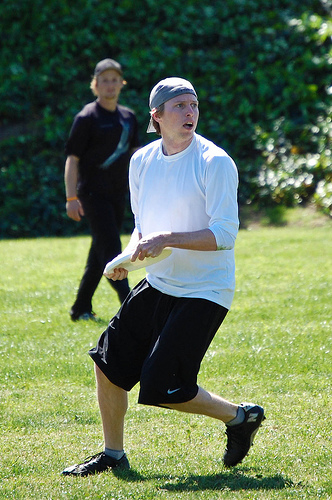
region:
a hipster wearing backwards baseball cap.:
[144, 77, 217, 145]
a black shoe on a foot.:
[217, 402, 269, 464]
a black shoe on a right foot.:
[58, 447, 135, 483]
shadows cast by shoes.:
[109, 466, 296, 499]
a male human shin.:
[90, 361, 131, 451]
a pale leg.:
[154, 386, 238, 421]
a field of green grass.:
[0, 204, 331, 497]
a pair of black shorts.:
[77, 280, 232, 399]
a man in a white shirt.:
[112, 134, 241, 310]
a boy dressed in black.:
[53, 47, 138, 314]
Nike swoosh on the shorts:
[154, 383, 187, 396]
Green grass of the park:
[14, 314, 66, 420]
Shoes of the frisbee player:
[52, 441, 147, 482]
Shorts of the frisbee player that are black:
[85, 281, 238, 404]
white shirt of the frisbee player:
[135, 131, 241, 308]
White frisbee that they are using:
[101, 237, 182, 276]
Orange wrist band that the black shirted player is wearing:
[53, 183, 87, 208]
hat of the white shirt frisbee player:
[148, 77, 209, 103]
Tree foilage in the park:
[200, 4, 329, 104]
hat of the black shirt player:
[90, 55, 123, 76]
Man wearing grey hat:
[148, 73, 194, 96]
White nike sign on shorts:
[161, 373, 182, 397]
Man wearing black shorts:
[108, 312, 198, 370]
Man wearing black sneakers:
[217, 393, 266, 471]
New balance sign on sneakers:
[245, 408, 257, 425]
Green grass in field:
[269, 353, 312, 416]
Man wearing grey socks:
[226, 398, 244, 426]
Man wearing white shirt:
[144, 180, 204, 220]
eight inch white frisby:
[111, 250, 129, 262]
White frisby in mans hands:
[82, 227, 185, 281]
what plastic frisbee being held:
[97, 238, 170, 279]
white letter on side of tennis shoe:
[244, 408, 262, 426]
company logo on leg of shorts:
[163, 381, 187, 399]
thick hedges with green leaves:
[241, 7, 330, 196]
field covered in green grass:
[13, 330, 77, 447]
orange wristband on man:
[59, 191, 82, 201]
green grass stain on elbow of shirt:
[210, 237, 236, 260]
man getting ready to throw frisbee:
[103, 92, 281, 388]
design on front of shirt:
[95, 114, 130, 176]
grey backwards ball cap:
[135, 77, 223, 133]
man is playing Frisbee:
[85, 219, 189, 295]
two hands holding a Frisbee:
[94, 222, 181, 290]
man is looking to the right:
[90, 69, 248, 285]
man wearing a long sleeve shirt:
[89, 69, 256, 340]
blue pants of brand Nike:
[83, 277, 230, 411]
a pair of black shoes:
[49, 398, 273, 477]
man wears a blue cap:
[115, 72, 246, 205]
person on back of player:
[65, 44, 139, 124]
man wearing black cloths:
[52, 48, 144, 322]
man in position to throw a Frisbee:
[76, 71, 272, 487]